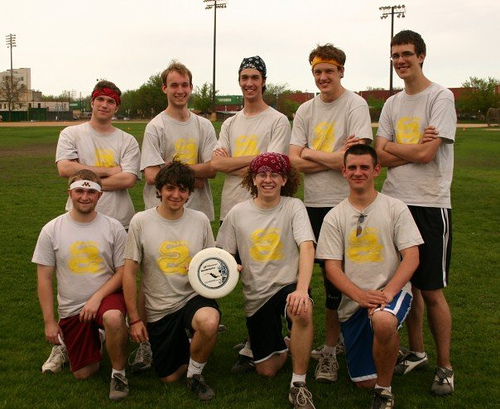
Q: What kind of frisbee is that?
A: A white frisbee.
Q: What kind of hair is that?
A: Brown hair.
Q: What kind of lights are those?
A: Football lights.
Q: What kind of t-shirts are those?
A: White t-shirts.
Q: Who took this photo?
A: Jackson Mingus.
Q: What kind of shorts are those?
A: Black shorts.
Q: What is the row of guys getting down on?
A: One knee.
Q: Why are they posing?
A: For a picture.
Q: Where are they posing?
A: On the field.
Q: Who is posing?
A: The team.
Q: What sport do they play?
A: Frisbee.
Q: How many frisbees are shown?
A: One.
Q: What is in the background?
A: Lights.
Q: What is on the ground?
A: Grass.